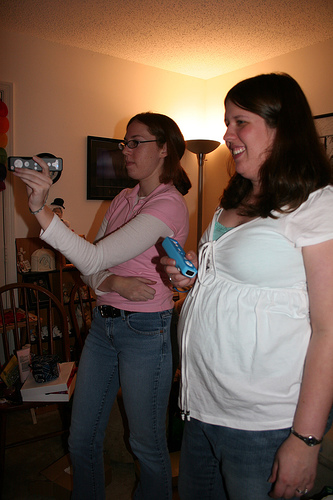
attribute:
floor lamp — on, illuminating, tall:
[182, 139, 220, 257]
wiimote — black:
[6, 156, 63, 173]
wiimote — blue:
[161, 237, 197, 279]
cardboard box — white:
[21, 361, 79, 403]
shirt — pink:
[95, 182, 189, 312]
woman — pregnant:
[160, 73, 332, 498]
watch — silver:
[288, 428, 323, 447]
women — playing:
[12, 72, 332, 499]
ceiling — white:
[0, 0, 332, 80]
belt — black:
[96, 304, 135, 319]